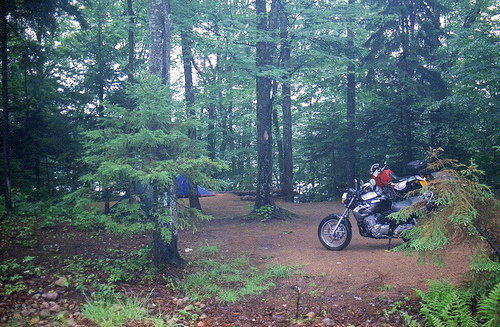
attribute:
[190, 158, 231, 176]
leaves — green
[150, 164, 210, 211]
tent — blue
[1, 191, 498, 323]
ground — brown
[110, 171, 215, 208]
tent — blue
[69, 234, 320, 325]
grass — green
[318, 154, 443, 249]
bike — black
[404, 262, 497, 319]
ferns — bright green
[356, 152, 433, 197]
bike —  red and black 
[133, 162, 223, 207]
tent — blue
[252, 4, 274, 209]
tree — GREY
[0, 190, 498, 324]
sand — brown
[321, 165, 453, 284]
bike — black and red